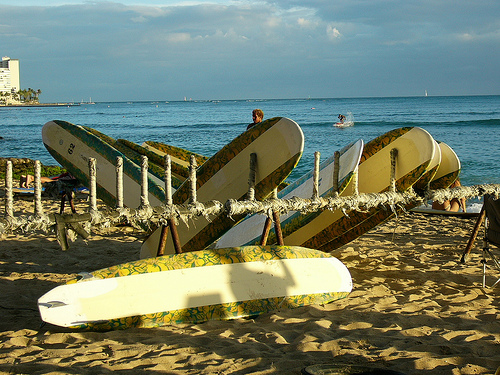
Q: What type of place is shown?
A: It is a beach.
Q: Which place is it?
A: It is a beach.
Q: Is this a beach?
A: Yes, it is a beach.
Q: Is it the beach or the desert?
A: It is the beach.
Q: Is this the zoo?
A: No, it is the beach.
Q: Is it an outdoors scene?
A: Yes, it is outdoors.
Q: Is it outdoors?
A: Yes, it is outdoors.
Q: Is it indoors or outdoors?
A: It is outdoors.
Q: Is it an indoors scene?
A: No, it is outdoors.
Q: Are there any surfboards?
A: Yes, there is a surfboard.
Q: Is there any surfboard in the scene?
A: Yes, there is a surfboard.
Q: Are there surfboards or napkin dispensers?
A: Yes, there is a surfboard.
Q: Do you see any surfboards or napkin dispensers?
A: Yes, there is a surfboard.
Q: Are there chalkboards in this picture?
A: No, there are no chalkboards.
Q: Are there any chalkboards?
A: No, there are no chalkboards.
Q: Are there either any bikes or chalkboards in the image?
A: No, there are no chalkboards or bikes.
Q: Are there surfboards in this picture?
A: Yes, there is a surfboard.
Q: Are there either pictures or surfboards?
A: Yes, there is a surfboard.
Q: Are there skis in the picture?
A: No, there are no skis.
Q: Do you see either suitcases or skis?
A: No, there are no skis or suitcases.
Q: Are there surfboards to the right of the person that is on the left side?
A: Yes, there is a surfboard to the right of the person.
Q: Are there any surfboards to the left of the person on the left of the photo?
A: No, the surfboard is to the right of the person.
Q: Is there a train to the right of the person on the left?
A: No, there is a surfboard to the right of the person.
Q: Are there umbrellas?
A: No, there are no umbrellas.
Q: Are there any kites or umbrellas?
A: No, there are no umbrellas or kites.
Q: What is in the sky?
A: The clouds are in the sky.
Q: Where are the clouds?
A: The clouds are in the sky.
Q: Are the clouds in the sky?
A: Yes, the clouds are in the sky.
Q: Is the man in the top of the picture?
A: Yes, the man is in the top of the image.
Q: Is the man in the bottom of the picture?
A: No, the man is in the top of the image.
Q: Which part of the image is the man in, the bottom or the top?
A: The man is in the top of the image.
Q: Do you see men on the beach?
A: Yes, there is a man on the beach.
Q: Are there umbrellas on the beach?
A: No, there is a man on the beach.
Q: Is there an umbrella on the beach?
A: No, there is a man on the beach.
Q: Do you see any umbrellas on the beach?
A: No, there is a man on the beach.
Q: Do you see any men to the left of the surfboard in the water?
A: Yes, there is a man to the left of the surf board.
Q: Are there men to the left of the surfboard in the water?
A: Yes, there is a man to the left of the surf board.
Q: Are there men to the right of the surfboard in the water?
A: No, the man is to the left of the surf board.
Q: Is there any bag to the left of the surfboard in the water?
A: No, there is a man to the left of the surfboard.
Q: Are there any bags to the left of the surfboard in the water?
A: No, there is a man to the left of the surfboard.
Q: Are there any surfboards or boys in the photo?
A: Yes, there is a surfboard.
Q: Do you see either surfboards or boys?
A: Yes, there is a surfboard.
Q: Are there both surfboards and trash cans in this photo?
A: No, there is a surfboard but no trash cans.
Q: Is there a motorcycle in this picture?
A: No, there are no motorcycles.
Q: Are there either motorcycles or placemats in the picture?
A: No, there are no motorcycles or placemats.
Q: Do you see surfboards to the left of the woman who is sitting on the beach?
A: Yes, there is a surfboard to the left of the woman.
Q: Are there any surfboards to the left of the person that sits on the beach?
A: Yes, there is a surfboard to the left of the woman.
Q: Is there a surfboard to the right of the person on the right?
A: No, the surfboard is to the left of the woman.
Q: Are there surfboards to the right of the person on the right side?
A: No, the surfboard is to the left of the woman.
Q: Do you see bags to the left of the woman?
A: No, there is a surfboard to the left of the woman.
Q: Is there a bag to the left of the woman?
A: No, there is a surfboard to the left of the woman.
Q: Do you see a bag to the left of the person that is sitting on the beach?
A: No, there is a surfboard to the left of the woman.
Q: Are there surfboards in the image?
A: Yes, there is a surfboard.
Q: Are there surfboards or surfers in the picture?
A: Yes, there is a surfboard.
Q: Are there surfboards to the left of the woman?
A: Yes, there is a surfboard to the left of the woman.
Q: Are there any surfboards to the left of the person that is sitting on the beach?
A: Yes, there is a surfboard to the left of the woman.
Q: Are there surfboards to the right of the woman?
A: No, the surfboard is to the left of the woman.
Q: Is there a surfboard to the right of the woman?
A: No, the surfboard is to the left of the woman.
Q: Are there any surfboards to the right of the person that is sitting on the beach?
A: No, the surfboard is to the left of the woman.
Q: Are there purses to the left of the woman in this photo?
A: No, there is a surfboard to the left of the woman.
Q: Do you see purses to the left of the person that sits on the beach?
A: No, there is a surfboard to the left of the woman.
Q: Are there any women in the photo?
A: Yes, there is a woman.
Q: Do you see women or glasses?
A: Yes, there is a woman.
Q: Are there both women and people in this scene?
A: Yes, there are both a woman and a person.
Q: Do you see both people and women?
A: Yes, there are both a woman and a person.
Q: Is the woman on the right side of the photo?
A: Yes, the woman is on the right of the image.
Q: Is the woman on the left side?
A: No, the woman is on the right of the image.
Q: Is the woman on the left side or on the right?
A: The woman is on the right of the image.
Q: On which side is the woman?
A: The woman is on the right of the image.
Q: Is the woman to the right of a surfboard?
A: Yes, the woman is to the right of a surfboard.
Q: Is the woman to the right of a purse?
A: No, the woman is to the right of a surfboard.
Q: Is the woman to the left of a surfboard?
A: No, the woman is to the right of a surfboard.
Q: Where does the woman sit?
A: The woman sits on the beach.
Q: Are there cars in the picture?
A: No, there are no cars.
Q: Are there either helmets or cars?
A: No, there are no cars or helmets.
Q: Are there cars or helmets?
A: No, there are no cars or helmets.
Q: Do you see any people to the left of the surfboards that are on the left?
A: Yes, there is a person to the left of the surfboards.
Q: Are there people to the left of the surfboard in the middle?
A: Yes, there is a person to the left of the surfboard.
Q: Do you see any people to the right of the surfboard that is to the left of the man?
A: No, the person is to the left of the surfboard.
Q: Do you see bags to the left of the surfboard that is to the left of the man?
A: No, there is a person to the left of the surfboard.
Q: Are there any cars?
A: No, there are no cars.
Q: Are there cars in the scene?
A: No, there are no cars.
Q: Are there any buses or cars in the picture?
A: No, there are no cars or buses.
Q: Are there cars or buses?
A: No, there are no cars or buses.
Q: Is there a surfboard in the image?
A: Yes, there is a surfboard.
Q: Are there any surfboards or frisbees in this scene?
A: Yes, there is a surfboard.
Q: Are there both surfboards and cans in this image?
A: No, there is a surfboard but no cans.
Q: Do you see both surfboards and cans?
A: No, there is a surfboard but no cans.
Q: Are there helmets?
A: No, there are no helmets.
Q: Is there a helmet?
A: No, there are no helmets.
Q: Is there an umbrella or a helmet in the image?
A: No, there are no helmets or umbrellas.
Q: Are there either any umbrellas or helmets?
A: No, there are no helmets or umbrellas.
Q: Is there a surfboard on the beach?
A: Yes, there is a surfboard on the beach.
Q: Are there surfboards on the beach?
A: Yes, there is a surfboard on the beach.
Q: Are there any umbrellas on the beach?
A: No, there is a surfboard on the beach.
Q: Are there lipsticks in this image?
A: No, there are no lipsticks.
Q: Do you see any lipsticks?
A: No, there are no lipsticks.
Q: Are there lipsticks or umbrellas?
A: No, there are no lipsticks or umbrellas.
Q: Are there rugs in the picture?
A: No, there are no rugs.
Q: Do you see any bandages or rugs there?
A: No, there are no rugs or bandages.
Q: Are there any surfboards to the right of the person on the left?
A: Yes, there are surfboards to the right of the person.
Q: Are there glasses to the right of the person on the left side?
A: No, there are surfboards to the right of the person.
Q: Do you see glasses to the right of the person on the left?
A: No, there are surfboards to the right of the person.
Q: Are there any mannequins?
A: No, there are no mannequins.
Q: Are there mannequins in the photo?
A: No, there are no mannequins.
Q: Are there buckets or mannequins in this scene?
A: No, there are no mannequins or buckets.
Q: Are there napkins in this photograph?
A: No, there are no napkins.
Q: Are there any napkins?
A: No, there are no napkins.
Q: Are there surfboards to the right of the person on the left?
A: Yes, there are surfboards to the right of the person.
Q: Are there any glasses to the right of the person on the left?
A: No, there are surfboards to the right of the person.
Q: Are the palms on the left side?
A: Yes, the palms are on the left of the image.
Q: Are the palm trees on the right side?
A: No, the palm trees are on the left of the image.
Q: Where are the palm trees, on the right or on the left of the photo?
A: The palm trees are on the left of the image.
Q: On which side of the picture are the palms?
A: The palms are on the left of the image.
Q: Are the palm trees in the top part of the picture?
A: Yes, the palm trees are in the top of the image.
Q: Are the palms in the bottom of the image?
A: No, the palms are in the top of the image.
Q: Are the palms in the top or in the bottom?
A: The palms are in the top of the image.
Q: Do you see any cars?
A: No, there are no cars.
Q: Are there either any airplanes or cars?
A: No, there are no cars or airplanes.